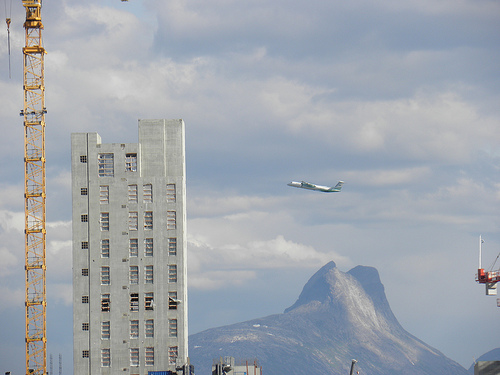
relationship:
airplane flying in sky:
[282, 180, 344, 194] [1, 0, 498, 367]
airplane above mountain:
[266, 169, 362, 215] [179, 258, 478, 369]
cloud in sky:
[0, 0, 499, 374] [1, 0, 498, 367]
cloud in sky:
[319, 162, 451, 190] [1, 0, 498, 367]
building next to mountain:
[59, 107, 211, 372] [210, 258, 462, 373]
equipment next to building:
[20, 2, 52, 374] [68, 105, 189, 374]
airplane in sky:
[282, 180, 344, 194] [1, 0, 498, 367]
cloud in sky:
[0, 0, 499, 374] [7, 6, 497, 334]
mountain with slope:
[177, 244, 435, 374] [344, 278, 434, 359]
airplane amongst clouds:
[282, 180, 344, 194] [18, 7, 497, 274]